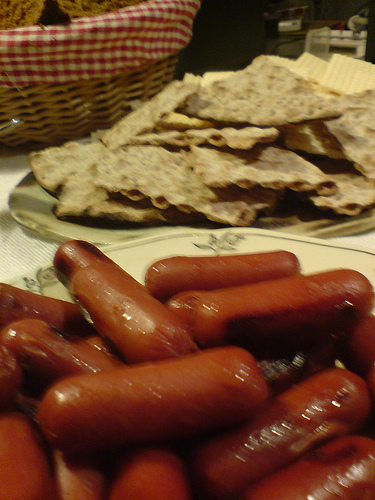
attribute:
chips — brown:
[19, 68, 334, 222]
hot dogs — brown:
[1, 239, 373, 498]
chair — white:
[300, 22, 333, 60]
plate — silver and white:
[24, 118, 362, 361]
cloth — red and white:
[3, 0, 191, 78]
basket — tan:
[0, 1, 200, 146]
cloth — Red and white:
[0, 0, 227, 83]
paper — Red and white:
[6, 4, 196, 79]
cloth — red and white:
[9, 8, 197, 73]